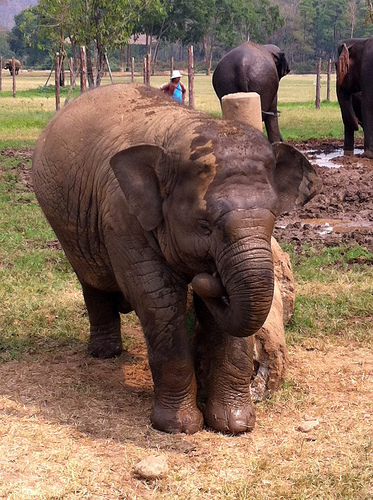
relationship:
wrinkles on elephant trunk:
[219, 234, 271, 330] [188, 223, 276, 338]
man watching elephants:
[159, 70, 186, 105] [204, 26, 372, 156]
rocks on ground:
[138, 415, 318, 472] [3, 330, 371, 498]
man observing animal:
[159, 70, 186, 105] [212, 42, 290, 143]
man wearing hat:
[159, 67, 189, 104] [168, 67, 185, 80]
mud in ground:
[272, 135, 373, 271] [32, 370, 349, 498]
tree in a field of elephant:
[188, 0, 263, 73] [334, 32, 371, 148]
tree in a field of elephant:
[242, 0, 286, 51] [211, 38, 287, 140]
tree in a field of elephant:
[157, 0, 224, 76] [28, 83, 320, 434]